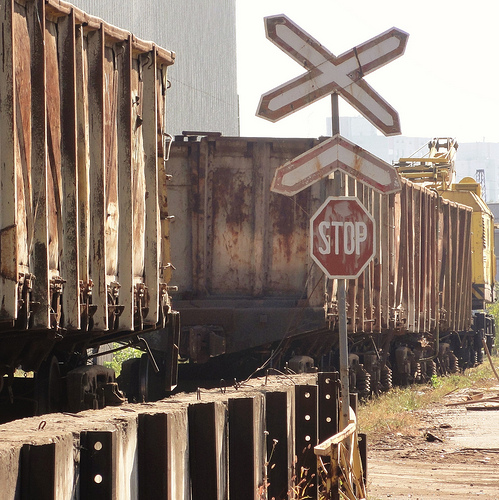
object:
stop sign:
[308, 196, 378, 280]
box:
[173, 133, 475, 396]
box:
[3, 0, 183, 341]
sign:
[254, 14, 409, 139]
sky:
[236, 3, 498, 204]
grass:
[355, 354, 498, 441]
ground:
[360, 354, 498, 499]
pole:
[329, 89, 350, 431]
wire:
[234, 259, 316, 388]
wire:
[265, 271, 324, 377]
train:
[161, 133, 498, 405]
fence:
[313, 404, 366, 499]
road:
[365, 356, 498, 500]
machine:
[396, 132, 461, 192]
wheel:
[438, 341, 461, 377]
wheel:
[393, 344, 418, 386]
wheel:
[364, 350, 388, 395]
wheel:
[290, 354, 318, 377]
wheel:
[33, 354, 69, 415]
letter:
[317, 220, 332, 256]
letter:
[331, 220, 344, 256]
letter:
[343, 221, 357, 256]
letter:
[354, 221, 368, 256]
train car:
[170, 130, 474, 398]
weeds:
[482, 301, 498, 351]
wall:
[0, 367, 344, 500]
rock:
[439, 422, 451, 430]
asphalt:
[418, 381, 498, 456]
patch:
[355, 354, 498, 445]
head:
[440, 178, 495, 309]